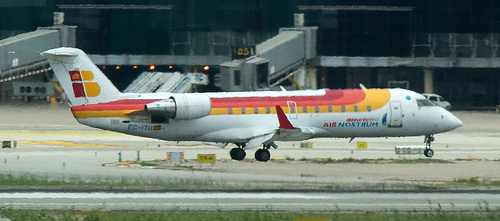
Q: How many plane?
A: 1.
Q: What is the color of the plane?
A: Mainly white.